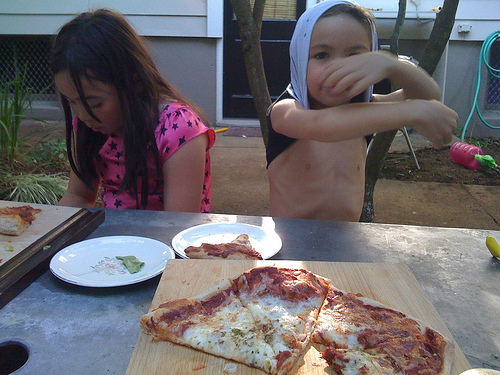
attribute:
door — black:
[221, 1, 301, 126]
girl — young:
[39, 30, 224, 226]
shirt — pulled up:
[67, 113, 215, 210]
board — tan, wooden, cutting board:
[168, 250, 449, 340]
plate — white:
[168, 219, 284, 266]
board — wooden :
[123, 258, 473, 374]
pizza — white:
[180, 226, 267, 266]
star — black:
[109, 195, 123, 209]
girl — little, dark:
[45, 9, 212, 216]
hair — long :
[47, 8, 165, 210]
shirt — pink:
[68, 99, 218, 215]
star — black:
[170, 122, 179, 131]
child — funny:
[251, 16, 435, 244]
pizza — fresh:
[137, 263, 458, 373]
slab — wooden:
[112, 241, 477, 372]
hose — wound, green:
[452, 32, 498, 137]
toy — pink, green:
[454, 126, 498, 173]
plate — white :
[176, 221, 274, 261]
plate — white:
[170, 220, 284, 259]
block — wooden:
[118, 257, 474, 371]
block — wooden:
[3, 195, 87, 273]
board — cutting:
[143, 257, 451, 373]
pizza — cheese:
[162, 261, 445, 371]